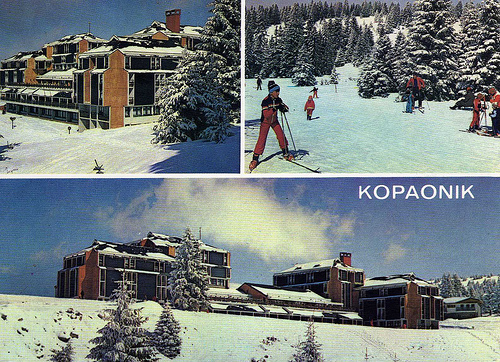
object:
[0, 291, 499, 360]
ground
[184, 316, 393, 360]
snow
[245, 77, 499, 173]
ground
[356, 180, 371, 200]
letter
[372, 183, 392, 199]
letter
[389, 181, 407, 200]
letter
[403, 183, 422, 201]
letter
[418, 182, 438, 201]
letter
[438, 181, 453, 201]
letter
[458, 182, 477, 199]
letter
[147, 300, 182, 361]
trees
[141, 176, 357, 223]
clouds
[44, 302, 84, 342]
rocks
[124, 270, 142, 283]
windows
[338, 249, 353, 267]
chimney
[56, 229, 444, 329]
lodge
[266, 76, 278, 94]
hat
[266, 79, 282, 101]
head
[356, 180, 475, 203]
name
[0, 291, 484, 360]
hill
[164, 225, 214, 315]
tree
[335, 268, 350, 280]
window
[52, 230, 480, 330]
building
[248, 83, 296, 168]
boy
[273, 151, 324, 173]
skis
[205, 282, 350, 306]
roof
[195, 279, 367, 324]
building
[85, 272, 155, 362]
tree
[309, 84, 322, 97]
people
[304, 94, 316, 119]
child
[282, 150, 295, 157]
shoe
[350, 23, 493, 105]
tree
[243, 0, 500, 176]
hill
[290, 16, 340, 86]
trees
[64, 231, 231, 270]
roofs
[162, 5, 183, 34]
chimney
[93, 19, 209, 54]
roof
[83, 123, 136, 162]
snow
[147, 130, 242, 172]
shadow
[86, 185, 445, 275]
sky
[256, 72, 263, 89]
people